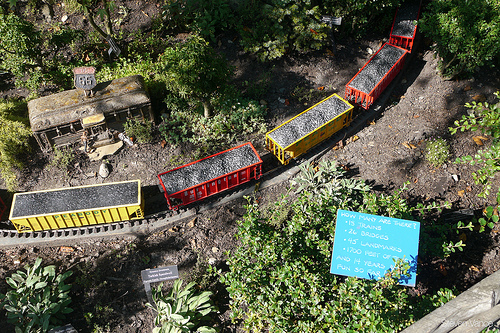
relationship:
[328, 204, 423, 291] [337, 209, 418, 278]
sign with writing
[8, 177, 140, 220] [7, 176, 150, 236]
coal in train car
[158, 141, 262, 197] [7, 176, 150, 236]
coal in train car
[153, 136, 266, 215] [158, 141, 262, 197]
train car with coal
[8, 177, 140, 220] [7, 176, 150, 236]
coal inside train car